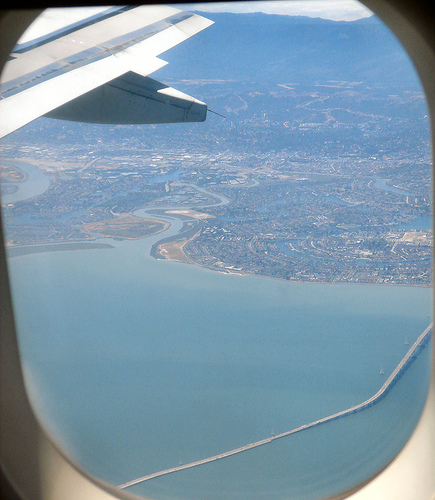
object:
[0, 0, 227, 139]
airplane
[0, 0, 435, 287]
land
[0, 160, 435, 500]
water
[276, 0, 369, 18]
sky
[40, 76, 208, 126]
housing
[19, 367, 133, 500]
frame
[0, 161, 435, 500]
river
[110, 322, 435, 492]
bridge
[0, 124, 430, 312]
delta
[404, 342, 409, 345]
boat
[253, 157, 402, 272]
homes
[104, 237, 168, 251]
mouth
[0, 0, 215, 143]
partial wing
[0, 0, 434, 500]
window